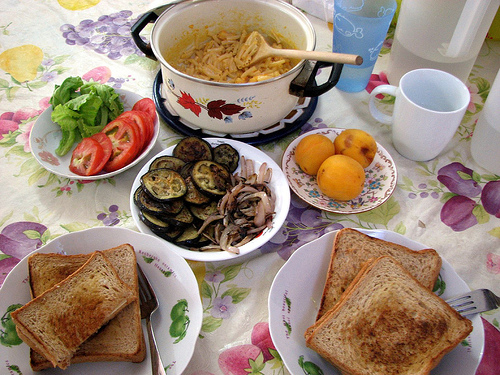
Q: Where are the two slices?
A: Plate.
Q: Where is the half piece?
A: On whole sclice.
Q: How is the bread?
A: Toasted.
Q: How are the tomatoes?
A: Scliced.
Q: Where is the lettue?
A: Bowl.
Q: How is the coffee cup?
A: White.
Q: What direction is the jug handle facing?
A: Toward viewer.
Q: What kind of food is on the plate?
A: Toast.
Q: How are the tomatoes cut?
A: Sliced.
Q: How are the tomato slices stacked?
A: Offset.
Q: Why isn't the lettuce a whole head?
A: It's been prepped for eating.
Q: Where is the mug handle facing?
A: To the left.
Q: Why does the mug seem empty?
A: No visible liquid.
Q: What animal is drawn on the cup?
A: Fish.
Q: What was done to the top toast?
A: Cut in half.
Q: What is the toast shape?
A: Square.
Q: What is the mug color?
A: White.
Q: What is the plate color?
A: White.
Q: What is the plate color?
A: White.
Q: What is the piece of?
A: Toast.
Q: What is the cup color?
A: White.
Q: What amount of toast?
A: Two.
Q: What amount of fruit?
A: Three.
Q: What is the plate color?
A: White.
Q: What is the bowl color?
A: White.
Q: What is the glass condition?
A: Empty.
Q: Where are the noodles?
A: Pot.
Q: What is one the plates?
A: Food.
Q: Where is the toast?
A: On plates.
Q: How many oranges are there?
A: Three.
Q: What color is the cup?
A: White.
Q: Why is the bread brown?
A: It was toasted.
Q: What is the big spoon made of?
A: Wood.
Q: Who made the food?
A: The cook.